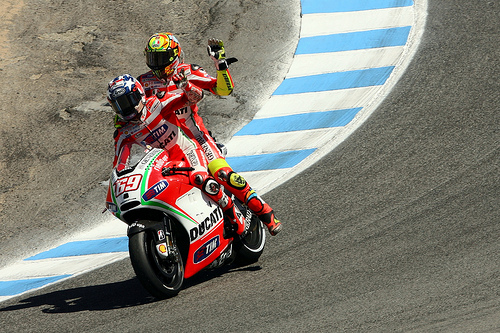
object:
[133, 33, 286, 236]
men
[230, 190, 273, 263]
back wheel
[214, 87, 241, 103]
hand up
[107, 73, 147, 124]
helmet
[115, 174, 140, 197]
69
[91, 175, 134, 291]
left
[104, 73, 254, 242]
driver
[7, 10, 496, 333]
road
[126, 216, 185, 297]
front wheel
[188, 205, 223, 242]
lettering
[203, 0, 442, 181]
curve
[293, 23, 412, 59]
lines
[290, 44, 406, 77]
lines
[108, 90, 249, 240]
suit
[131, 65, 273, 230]
suit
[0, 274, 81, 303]
line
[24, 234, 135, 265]
line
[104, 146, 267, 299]
bike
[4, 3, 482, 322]
dirt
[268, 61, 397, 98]
line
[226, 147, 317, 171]
line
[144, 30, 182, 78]
helmet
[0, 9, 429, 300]
stripes